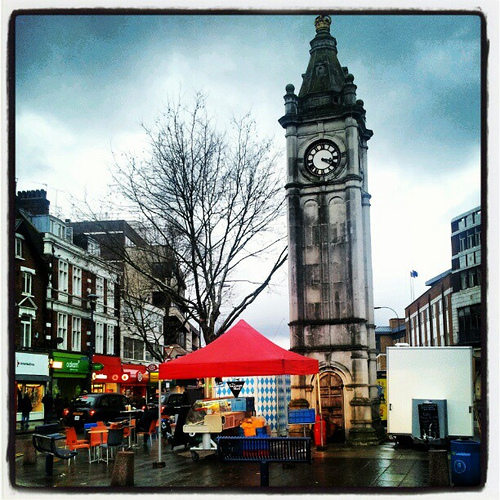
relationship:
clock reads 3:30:
[303, 137, 347, 177] [321, 148, 337, 169]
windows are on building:
[58, 263, 113, 353] [27, 187, 118, 377]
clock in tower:
[303, 137, 347, 177] [270, 13, 382, 444]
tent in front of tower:
[155, 322, 327, 460] [270, 13, 382, 444]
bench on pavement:
[214, 436, 311, 485] [17, 388, 484, 500]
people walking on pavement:
[23, 384, 78, 429] [17, 388, 484, 500]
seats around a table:
[67, 422, 137, 467] [90, 429, 109, 449]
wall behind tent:
[212, 374, 287, 440] [155, 322, 327, 460]